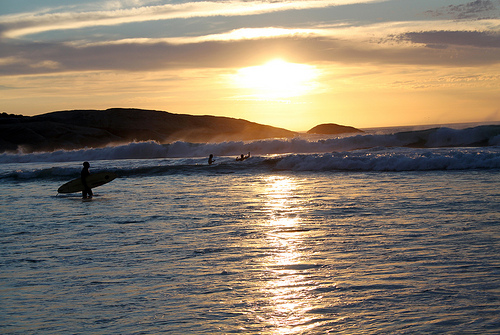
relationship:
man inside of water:
[80, 161, 97, 203] [24, 208, 155, 264]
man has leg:
[80, 161, 97, 203] [80, 190, 85, 199]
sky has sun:
[1, 1, 500, 134] [243, 54, 324, 104]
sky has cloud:
[1, 1, 500, 134] [393, 30, 483, 50]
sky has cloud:
[1, 1, 500, 134] [179, 31, 265, 61]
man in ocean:
[73, 163, 99, 203] [10, 150, 484, 328]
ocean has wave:
[10, 150, 484, 328] [290, 199, 374, 224]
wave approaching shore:
[6, 143, 481, 170] [12, 132, 482, 177]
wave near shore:
[2, 143, 500, 186] [13, 137, 483, 180]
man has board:
[80, 161, 97, 203] [52, 168, 124, 194]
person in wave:
[203, 149, 218, 167] [189, 142, 475, 185]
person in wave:
[232, 147, 249, 157] [189, 142, 475, 185]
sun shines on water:
[233, 54, 312, 102] [24, 150, 481, 284]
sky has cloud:
[1, 1, 500, 134] [99, 42, 248, 71]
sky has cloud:
[1, 1, 500, 134] [131, 10, 307, 34]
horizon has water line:
[264, 107, 483, 125] [370, 120, 483, 129]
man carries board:
[80, 161, 97, 203] [52, 170, 121, 194]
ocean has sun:
[0, 122, 500, 335] [259, 194, 315, 312]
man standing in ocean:
[80, 161, 97, 203] [20, 148, 482, 282]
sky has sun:
[1, 1, 500, 134] [235, 55, 330, 114]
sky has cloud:
[1, 6, 480, 133] [88, 41, 241, 69]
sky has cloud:
[1, 6, 480, 133] [124, 15, 283, 35]